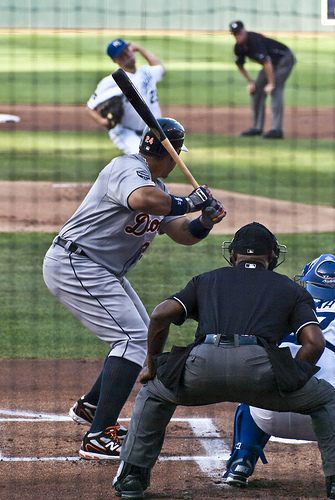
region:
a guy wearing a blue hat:
[98, 35, 148, 68]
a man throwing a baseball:
[90, 31, 162, 69]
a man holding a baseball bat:
[122, 86, 250, 238]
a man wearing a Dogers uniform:
[83, 184, 178, 258]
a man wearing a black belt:
[49, 226, 99, 262]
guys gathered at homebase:
[65, 181, 331, 460]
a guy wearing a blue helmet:
[299, 251, 334, 298]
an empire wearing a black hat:
[226, 221, 300, 273]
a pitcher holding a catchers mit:
[85, 90, 136, 134]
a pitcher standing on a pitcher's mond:
[102, 40, 160, 139]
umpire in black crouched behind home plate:
[111, 220, 334, 498]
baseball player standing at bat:
[43, 66, 229, 461]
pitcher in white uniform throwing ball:
[84, 37, 167, 154]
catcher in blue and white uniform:
[222, 251, 334, 486]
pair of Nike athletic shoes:
[67, 393, 128, 460]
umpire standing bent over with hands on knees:
[228, 19, 298, 140]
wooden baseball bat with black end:
[110, 66, 201, 190]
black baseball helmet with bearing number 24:
[138, 116, 189, 160]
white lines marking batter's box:
[1, 415, 233, 462]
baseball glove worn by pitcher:
[99, 93, 125, 131]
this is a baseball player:
[28, 70, 209, 469]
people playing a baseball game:
[38, 9, 331, 486]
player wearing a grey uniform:
[43, 140, 173, 389]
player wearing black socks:
[73, 326, 149, 429]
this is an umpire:
[111, 185, 332, 493]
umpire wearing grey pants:
[121, 312, 333, 494]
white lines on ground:
[2, 376, 267, 498]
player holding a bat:
[92, 48, 232, 230]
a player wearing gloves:
[164, 176, 244, 245]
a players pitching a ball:
[86, 28, 187, 192]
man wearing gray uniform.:
[53, 92, 152, 470]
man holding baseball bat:
[58, 73, 220, 498]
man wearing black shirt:
[219, 14, 301, 144]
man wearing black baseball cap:
[223, 20, 304, 143]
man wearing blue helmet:
[229, 238, 331, 479]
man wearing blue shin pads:
[214, 236, 333, 483]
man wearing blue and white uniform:
[96, 32, 185, 166]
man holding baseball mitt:
[82, 28, 186, 178]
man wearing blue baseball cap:
[96, 28, 176, 171]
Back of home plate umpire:
[112, 219, 333, 497]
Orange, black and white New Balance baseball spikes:
[68, 394, 129, 461]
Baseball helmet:
[139, 117, 189, 160]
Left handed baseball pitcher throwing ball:
[87, 37, 164, 156]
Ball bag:
[258, 334, 320, 395]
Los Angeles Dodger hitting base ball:
[41, 117, 227, 458]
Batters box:
[1, 413, 233, 462]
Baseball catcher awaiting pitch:
[217, 255, 333, 487]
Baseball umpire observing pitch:
[226, 18, 297, 140]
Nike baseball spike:
[223, 458, 254, 486]